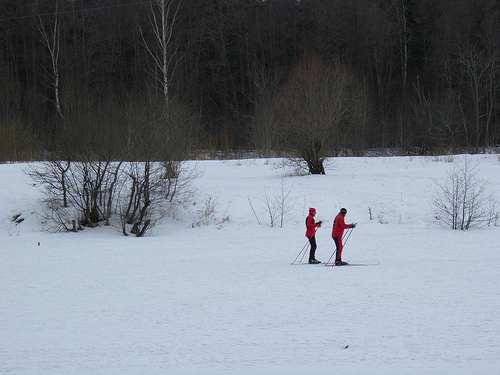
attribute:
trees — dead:
[1, 2, 499, 234]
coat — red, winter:
[305, 217, 321, 238]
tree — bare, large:
[33, 2, 69, 125]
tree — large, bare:
[134, 0, 199, 176]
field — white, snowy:
[67, 269, 372, 343]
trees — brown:
[244, 51, 389, 111]